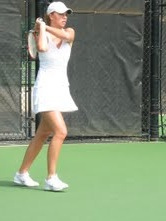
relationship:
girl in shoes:
[13, 0, 80, 193] [12, 170, 70, 191]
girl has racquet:
[13, 0, 80, 193] [27, 26, 39, 60]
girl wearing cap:
[13, 0, 80, 193] [46, 1, 74, 16]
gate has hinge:
[1, 0, 33, 142] [25, 116, 36, 124]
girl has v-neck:
[13, 0, 80, 193] [48, 30, 65, 53]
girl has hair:
[13, 0, 80, 193] [45, 13, 52, 25]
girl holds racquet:
[13, 0, 80, 193] [27, 26, 39, 60]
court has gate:
[0, 142, 165, 221] [1, 0, 33, 142]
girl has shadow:
[13, 0, 80, 193] [0, 180, 33, 190]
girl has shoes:
[13, 0, 80, 193] [12, 170, 70, 191]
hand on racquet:
[35, 17, 47, 28] [27, 26, 39, 60]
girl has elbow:
[13, 0, 80, 193] [37, 42, 49, 52]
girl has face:
[13, 0, 80, 193] [55, 11, 69, 29]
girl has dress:
[13, 0, 80, 193] [32, 30, 79, 116]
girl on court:
[13, 0, 80, 193] [0, 142, 165, 221]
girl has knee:
[13, 0, 80, 193] [54, 127, 69, 140]